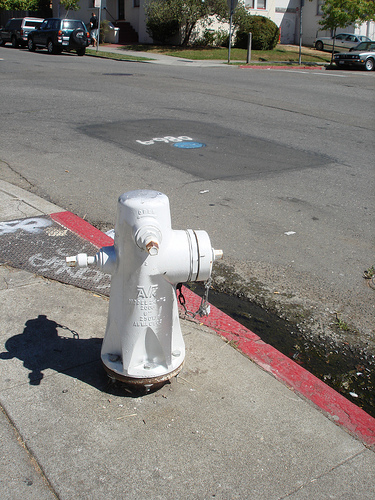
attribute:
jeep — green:
[9, 10, 90, 51]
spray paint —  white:
[1, 213, 51, 244]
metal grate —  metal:
[0, 213, 109, 297]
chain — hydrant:
[175, 282, 214, 318]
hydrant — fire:
[56, 185, 230, 394]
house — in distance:
[98, 9, 299, 41]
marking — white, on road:
[134, 132, 197, 147]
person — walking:
[88, 11, 100, 47]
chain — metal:
[178, 277, 214, 320]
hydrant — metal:
[58, 172, 226, 397]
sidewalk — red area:
[199, 294, 349, 435]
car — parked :
[333, 38, 373, 69]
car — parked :
[313, 29, 366, 56]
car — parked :
[30, 17, 90, 52]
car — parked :
[2, 11, 43, 46]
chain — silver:
[176, 286, 216, 319]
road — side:
[5, 52, 372, 389]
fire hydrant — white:
[98, 189, 223, 389]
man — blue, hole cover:
[70, 9, 119, 57]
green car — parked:
[34, 16, 97, 49]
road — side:
[86, 71, 246, 105]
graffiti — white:
[9, 203, 59, 273]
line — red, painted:
[196, 298, 361, 435]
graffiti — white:
[20, 208, 57, 275]